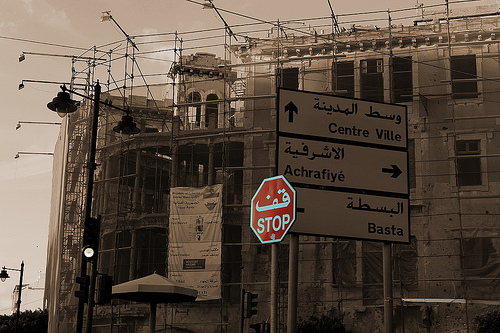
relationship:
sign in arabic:
[275, 86, 409, 248] [309, 95, 405, 127]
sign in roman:
[275, 86, 409, 248] [283, 163, 354, 185]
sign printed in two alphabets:
[275, 86, 409, 248] [314, 92, 409, 147]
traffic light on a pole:
[82, 216, 97, 261] [88, 218, 99, 332]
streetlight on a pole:
[46, 84, 78, 121] [76, 84, 102, 331]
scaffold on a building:
[73, 2, 497, 94] [15, 22, 500, 331]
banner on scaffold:
[165, 184, 226, 302] [73, 2, 497, 94]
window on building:
[446, 49, 486, 104] [15, 22, 500, 331]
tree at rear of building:
[1, 308, 43, 333] [15, 22, 500, 331]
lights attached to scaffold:
[14, 47, 81, 163] [73, 2, 497, 94]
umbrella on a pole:
[110, 270, 200, 304] [149, 300, 159, 332]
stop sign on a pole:
[249, 173, 296, 243] [268, 246, 276, 331]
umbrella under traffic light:
[110, 270, 200, 304] [82, 216, 97, 261]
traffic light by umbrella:
[74, 217, 114, 306] [110, 270, 200, 304]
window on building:
[455, 131, 483, 189] [15, 22, 500, 331]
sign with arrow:
[275, 86, 409, 248] [284, 99, 303, 127]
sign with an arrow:
[275, 86, 409, 248] [381, 163, 403, 179]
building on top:
[15, 22, 500, 331] [52, 38, 500, 140]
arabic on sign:
[309, 95, 405, 127] [275, 86, 409, 248]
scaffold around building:
[73, 2, 497, 94] [15, 22, 500, 331]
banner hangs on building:
[165, 184, 226, 302] [15, 22, 500, 331]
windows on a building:
[331, 52, 415, 107] [15, 22, 500, 331]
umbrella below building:
[110, 270, 200, 304] [15, 22, 500, 331]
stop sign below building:
[249, 173, 296, 243] [15, 22, 500, 331]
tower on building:
[169, 54, 239, 129] [15, 22, 500, 331]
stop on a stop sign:
[257, 214, 292, 232] [249, 173, 296, 243]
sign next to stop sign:
[275, 86, 409, 248] [249, 173, 296, 243]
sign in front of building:
[275, 86, 409, 248] [15, 22, 500, 331]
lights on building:
[14, 47, 81, 163] [15, 22, 500, 331]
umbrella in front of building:
[110, 270, 200, 304] [15, 22, 500, 331]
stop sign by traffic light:
[249, 173, 296, 243] [82, 216, 97, 261]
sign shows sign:
[275, 86, 409, 248] [275, 86, 409, 248]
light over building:
[102, 9, 139, 48] [15, 22, 500, 331]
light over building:
[15, 47, 101, 66] [15, 22, 500, 331]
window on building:
[331, 52, 415, 107] [15, 22, 500, 331]